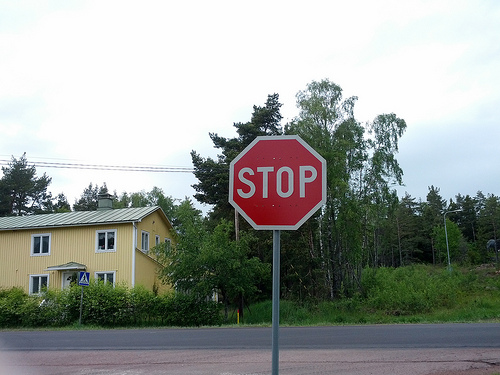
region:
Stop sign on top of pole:
[227, 134, 328, 374]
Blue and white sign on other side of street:
[78, 270, 90, 325]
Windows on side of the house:
[30, 229, 117, 296]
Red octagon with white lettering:
[228, 134, 328, 233]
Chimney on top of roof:
[93, 191, 114, 210]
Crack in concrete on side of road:
[466, 354, 499, 374]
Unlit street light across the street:
[442, 208, 464, 270]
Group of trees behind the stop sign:
[148, 87, 408, 326]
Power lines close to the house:
[0, 158, 196, 174]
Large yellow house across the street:
[2, 192, 181, 325]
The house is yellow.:
[116, 238, 131, 271]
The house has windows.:
[28, 230, 117, 257]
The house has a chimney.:
[94, 194, 114, 213]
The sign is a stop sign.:
[227, 135, 326, 229]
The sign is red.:
[260, 140, 297, 163]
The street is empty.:
[288, 323, 494, 373]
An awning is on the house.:
[47, 260, 85, 272]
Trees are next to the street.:
[233, 80, 406, 135]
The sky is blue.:
[413, 134, 486, 176]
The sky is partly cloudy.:
[33, 78, 196, 138]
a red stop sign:
[232, 130, 330, 232]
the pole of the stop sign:
[259, 231, 294, 373]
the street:
[11, 328, 496, 355]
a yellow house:
[4, 212, 183, 303]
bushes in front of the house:
[21, 287, 213, 320]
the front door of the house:
[63, 272, 77, 285]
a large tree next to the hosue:
[169, 85, 406, 274]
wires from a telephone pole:
[10, 152, 212, 188]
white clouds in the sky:
[53, 44, 264, 106]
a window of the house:
[93, 230, 115, 249]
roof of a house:
[6, 202, 170, 239]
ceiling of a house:
[7, 189, 155, 227]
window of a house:
[90, 232, 128, 257]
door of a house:
[57, 261, 85, 303]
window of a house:
[25, 275, 57, 309]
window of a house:
[92, 262, 120, 292]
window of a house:
[132, 226, 150, 246]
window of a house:
[152, 235, 164, 253]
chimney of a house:
[93, 189, 121, 211]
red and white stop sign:
[196, 135, 322, 222]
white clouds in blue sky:
[53, 51, 124, 83]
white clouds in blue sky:
[423, 57, 480, 120]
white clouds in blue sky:
[357, 25, 426, 65]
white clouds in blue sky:
[133, 70, 226, 137]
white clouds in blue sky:
[23, 29, 71, 75]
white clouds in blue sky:
[102, 23, 189, 98]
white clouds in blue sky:
[21, 61, 102, 132]